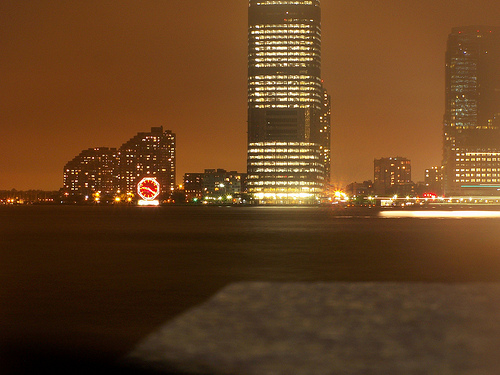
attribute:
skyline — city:
[1, 0, 498, 220]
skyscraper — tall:
[247, 2, 322, 207]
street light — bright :
[134, 176, 160, 208]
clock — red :
[135, 178, 160, 200]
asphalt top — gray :
[123, 255, 497, 373]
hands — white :
[135, 171, 160, 198]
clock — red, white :
[134, 173, 164, 205]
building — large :
[60, 136, 129, 219]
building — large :
[110, 124, 180, 205]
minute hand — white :
[142, 185, 154, 195]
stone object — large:
[127, 282, 499, 374]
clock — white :
[134, 173, 166, 213]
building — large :
[371, 154, 412, 193]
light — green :
[460, 183, 498, 188]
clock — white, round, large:
[134, 175, 160, 197]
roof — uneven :
[80, 120, 172, 152]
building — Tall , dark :
[244, 2, 334, 207]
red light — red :
[488, 30, 495, 33]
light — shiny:
[329, 182, 351, 204]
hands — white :
[140, 184, 157, 196]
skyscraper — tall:
[430, 23, 483, 197]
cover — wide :
[132, 259, 493, 366]